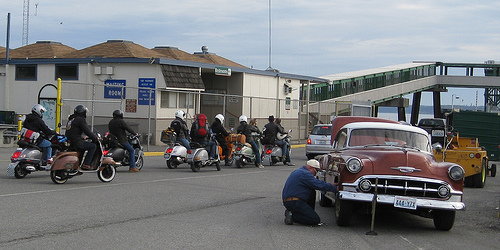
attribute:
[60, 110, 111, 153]
jacket — black, gray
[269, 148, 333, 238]
shirt — blue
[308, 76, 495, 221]
car — brown, parked, vintage, broke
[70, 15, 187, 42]
sky — blue, clear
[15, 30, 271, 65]
roof — brown, triangle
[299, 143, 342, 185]
cap — white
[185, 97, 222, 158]
bag — red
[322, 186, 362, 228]
tires — black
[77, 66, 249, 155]
walls — beige, silver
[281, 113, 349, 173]
car — silver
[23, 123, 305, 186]
bikes — stopped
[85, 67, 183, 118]
sign — blue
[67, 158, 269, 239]
street — gray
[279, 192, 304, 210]
belt — brown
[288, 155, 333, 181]
man — old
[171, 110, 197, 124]
helmet — white, silver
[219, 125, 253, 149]
bag — brown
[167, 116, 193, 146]
jacket — gray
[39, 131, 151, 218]
bike — brown, silver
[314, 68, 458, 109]
bridge — green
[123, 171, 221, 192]
line — white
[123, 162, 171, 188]
shoes — brown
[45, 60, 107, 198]
pole — yellow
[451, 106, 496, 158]
metal — green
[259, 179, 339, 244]
jeans — blue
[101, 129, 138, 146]
seat — black